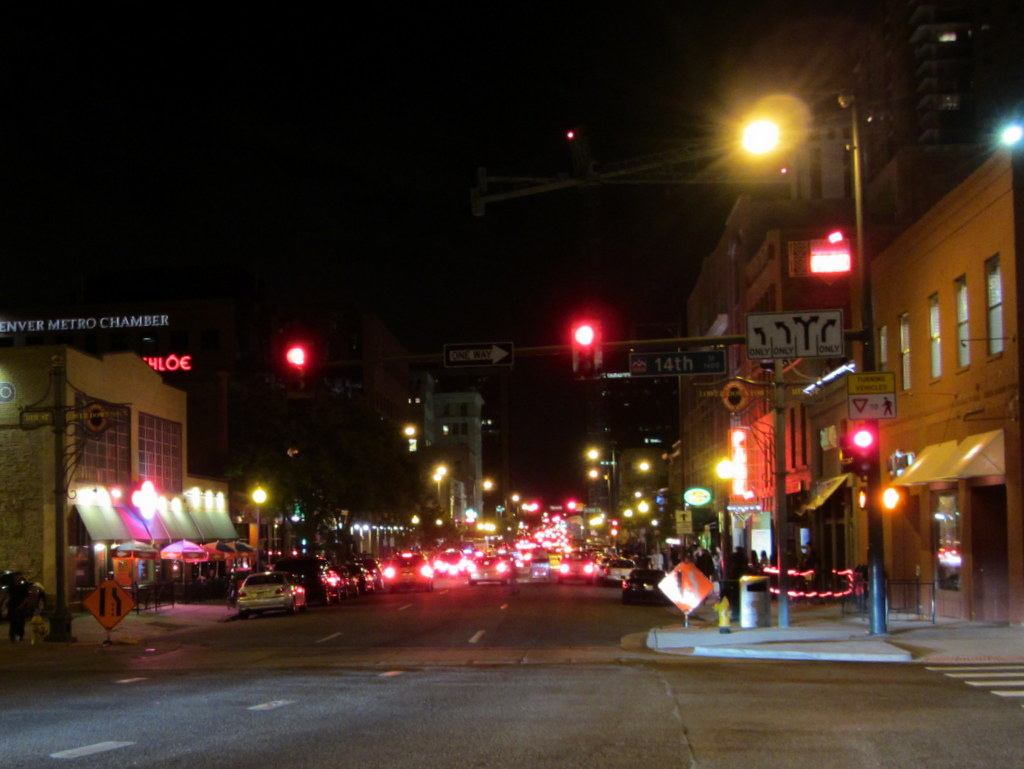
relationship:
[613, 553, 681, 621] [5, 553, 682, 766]
car on road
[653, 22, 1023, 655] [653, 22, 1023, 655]
wall on side of building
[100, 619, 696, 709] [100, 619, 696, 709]
intersection at an crosswalk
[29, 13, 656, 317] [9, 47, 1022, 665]
sky above buildings